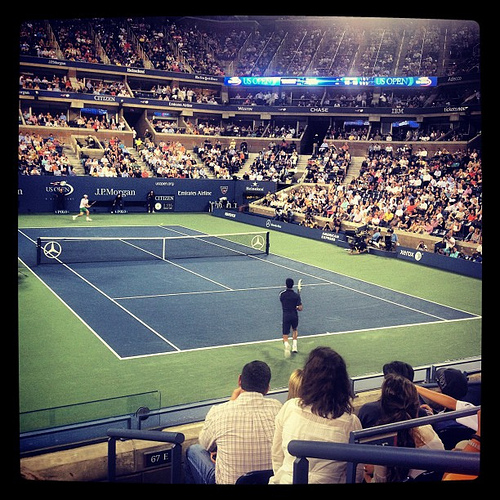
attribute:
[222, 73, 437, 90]
scoreboard — tennis, match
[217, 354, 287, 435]
spectator — male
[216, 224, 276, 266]
logo — tennis, match, sponsor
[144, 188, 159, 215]
boy — ball, dressed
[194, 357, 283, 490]
spectator — dressed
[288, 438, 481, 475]
top rail — metal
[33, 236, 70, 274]
marker — white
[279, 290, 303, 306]
shirt — black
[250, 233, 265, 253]
logo — mercedes benz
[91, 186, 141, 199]
jp morgan — white, blue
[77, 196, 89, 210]
shirt — white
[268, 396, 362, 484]
shirt — white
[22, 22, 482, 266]
seating — indoor, arena